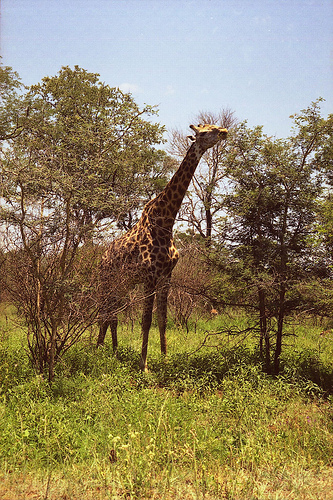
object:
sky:
[0, 0, 331, 273]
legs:
[141, 276, 171, 371]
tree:
[0, 62, 172, 391]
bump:
[166, 244, 182, 269]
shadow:
[180, 344, 333, 408]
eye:
[201, 131, 207, 134]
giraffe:
[90, 122, 235, 380]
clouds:
[0, 0, 333, 107]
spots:
[95, 155, 200, 295]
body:
[90, 201, 182, 292]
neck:
[154, 140, 203, 222]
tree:
[195, 89, 333, 374]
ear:
[186, 135, 197, 143]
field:
[0, 296, 333, 500]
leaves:
[208, 98, 333, 220]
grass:
[0, 287, 333, 500]